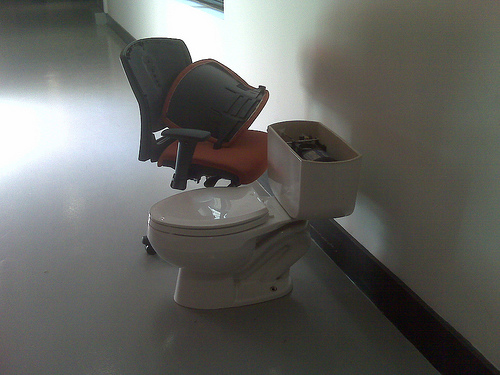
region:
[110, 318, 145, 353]
part of a floor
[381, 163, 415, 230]
part of a shade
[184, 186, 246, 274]
edge of a toilet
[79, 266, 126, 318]
part of a floor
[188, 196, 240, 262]
edge of a lid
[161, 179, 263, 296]
this is a toilet sink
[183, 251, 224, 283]
the sink is white in color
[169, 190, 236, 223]
this is the lid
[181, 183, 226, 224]
the lid is white in color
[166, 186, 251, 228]
the lid is covered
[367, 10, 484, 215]
this is the wall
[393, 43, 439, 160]
the wall is white in color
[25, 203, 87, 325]
this is the floor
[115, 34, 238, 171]
this is a chair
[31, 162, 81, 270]
the floor is slippery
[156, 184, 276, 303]
this is a toilet sink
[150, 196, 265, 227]
this is the lid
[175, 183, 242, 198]
the lid is white in color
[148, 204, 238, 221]
the lid is covered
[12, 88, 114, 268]
this is the floor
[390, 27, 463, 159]
this is the wall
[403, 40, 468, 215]
the wall is white in color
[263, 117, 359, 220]
A white toilet tank with no lid.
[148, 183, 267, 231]
A white shiny toilet seat.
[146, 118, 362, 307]
A white toilet.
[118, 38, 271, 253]
A broken red and black desk chair.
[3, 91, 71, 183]
Bright white reflection on the floor.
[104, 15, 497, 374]
Black trim at the bottom of the wall.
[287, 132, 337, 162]
The guts of the toilet inside the toilet tank.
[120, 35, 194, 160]
The black back of the desk chair.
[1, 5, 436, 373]
A grey floor.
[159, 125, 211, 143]
A black chair arm.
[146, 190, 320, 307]
A white toilet seat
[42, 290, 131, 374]
A white toilet floor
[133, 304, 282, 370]
A white toilet floor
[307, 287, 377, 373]
A white toilet floor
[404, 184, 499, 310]
A white toilet wall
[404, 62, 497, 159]
A white toilet wall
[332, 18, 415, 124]
A white toilet wall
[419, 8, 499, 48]
A white toilet wall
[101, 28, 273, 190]
A broken orange seat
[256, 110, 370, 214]
A broken water holder